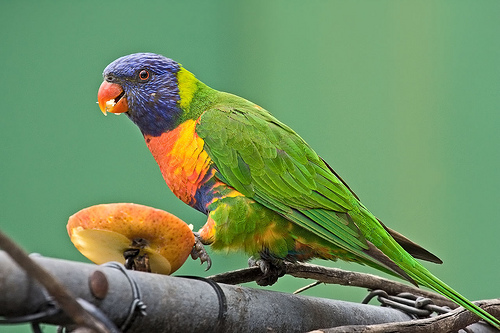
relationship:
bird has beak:
[94, 42, 497, 326] [94, 81, 129, 116]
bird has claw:
[94, 42, 497, 326] [179, 221, 220, 269]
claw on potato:
[179, 221, 220, 269] [64, 201, 197, 271]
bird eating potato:
[94, 42, 497, 326] [64, 201, 197, 271]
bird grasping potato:
[94, 42, 497, 326] [64, 201, 197, 271]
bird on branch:
[94, 42, 497, 326] [1, 253, 499, 333]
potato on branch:
[64, 201, 197, 271] [1, 253, 499, 333]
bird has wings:
[94, 42, 497, 326] [198, 80, 498, 327]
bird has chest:
[94, 42, 497, 326] [140, 119, 219, 205]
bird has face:
[94, 42, 497, 326] [105, 52, 185, 138]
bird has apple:
[94, 42, 497, 326] [64, 201, 197, 271]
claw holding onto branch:
[179, 221, 220, 269] [1, 253, 499, 333]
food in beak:
[102, 97, 117, 112] [94, 81, 129, 116]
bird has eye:
[94, 42, 497, 326] [135, 68, 152, 83]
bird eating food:
[94, 42, 497, 326] [102, 97, 117, 112]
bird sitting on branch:
[94, 42, 497, 326] [1, 253, 499, 333]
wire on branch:
[104, 258, 152, 332] [1, 253, 499, 333]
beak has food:
[94, 81, 129, 116] [102, 97, 117, 112]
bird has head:
[94, 42, 497, 326] [92, 50, 199, 137]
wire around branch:
[104, 258, 152, 332] [1, 253, 499, 333]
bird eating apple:
[94, 42, 497, 326] [64, 201, 197, 271]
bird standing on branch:
[94, 42, 497, 326] [1, 253, 499, 333]